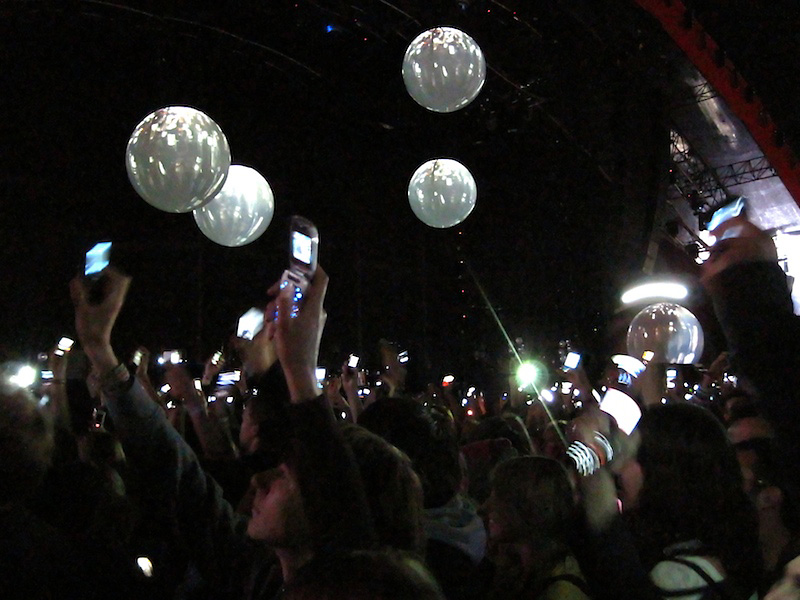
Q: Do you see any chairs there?
A: No, there are no chairs.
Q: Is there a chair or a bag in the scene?
A: No, there are no chairs or bags.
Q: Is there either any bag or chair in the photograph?
A: No, there are no chairs or bags.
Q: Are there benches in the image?
A: No, there are no benches.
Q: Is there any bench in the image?
A: No, there are no benches.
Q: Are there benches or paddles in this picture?
A: No, there are no benches or paddles.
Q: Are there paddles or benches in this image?
A: No, there are no benches or paddles.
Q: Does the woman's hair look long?
A: Yes, the hair is long.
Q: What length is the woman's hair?
A: The hair is long.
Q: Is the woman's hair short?
A: No, the hair is long.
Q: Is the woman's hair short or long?
A: The hair is long.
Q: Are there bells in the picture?
A: No, there are no bells.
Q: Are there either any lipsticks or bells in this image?
A: No, there are no bells or lipsticks.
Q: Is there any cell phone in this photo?
A: Yes, there is a cell phone.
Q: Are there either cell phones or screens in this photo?
A: Yes, there is a cell phone.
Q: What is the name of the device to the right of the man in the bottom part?
A: The device is a cell phone.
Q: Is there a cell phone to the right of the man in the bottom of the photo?
A: Yes, there is a cell phone to the right of the man.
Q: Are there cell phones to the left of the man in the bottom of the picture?
A: No, the cell phone is to the right of the man.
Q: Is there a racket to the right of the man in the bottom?
A: No, there is a cell phone to the right of the man.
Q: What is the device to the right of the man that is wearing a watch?
A: The device is a cell phone.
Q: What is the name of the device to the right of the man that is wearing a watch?
A: The device is a cell phone.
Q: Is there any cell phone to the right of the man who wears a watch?
A: Yes, there is a cell phone to the right of the man.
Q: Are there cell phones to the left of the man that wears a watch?
A: No, the cell phone is to the right of the man.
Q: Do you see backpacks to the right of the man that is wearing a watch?
A: No, there is a cell phone to the right of the man.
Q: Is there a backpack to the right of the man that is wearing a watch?
A: No, there is a cell phone to the right of the man.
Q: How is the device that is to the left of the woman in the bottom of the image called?
A: The device is a cell phone.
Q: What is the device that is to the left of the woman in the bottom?
A: The device is a cell phone.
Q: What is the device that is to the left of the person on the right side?
A: The device is a cell phone.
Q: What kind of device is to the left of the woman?
A: The device is a cell phone.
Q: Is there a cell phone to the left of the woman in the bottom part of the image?
A: Yes, there is a cell phone to the left of the woman.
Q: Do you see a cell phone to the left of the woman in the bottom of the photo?
A: Yes, there is a cell phone to the left of the woman.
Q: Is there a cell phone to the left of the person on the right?
A: Yes, there is a cell phone to the left of the woman.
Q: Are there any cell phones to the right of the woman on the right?
A: No, the cell phone is to the left of the woman.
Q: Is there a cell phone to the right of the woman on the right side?
A: No, the cell phone is to the left of the woman.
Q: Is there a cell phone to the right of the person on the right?
A: No, the cell phone is to the left of the woman.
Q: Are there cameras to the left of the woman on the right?
A: No, there is a cell phone to the left of the woman.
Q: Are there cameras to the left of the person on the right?
A: No, there is a cell phone to the left of the woman.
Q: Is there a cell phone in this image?
A: Yes, there is a cell phone.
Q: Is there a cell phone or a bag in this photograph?
A: Yes, there is a cell phone.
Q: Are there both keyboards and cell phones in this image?
A: No, there is a cell phone but no keyboards.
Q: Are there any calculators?
A: No, there are no calculators.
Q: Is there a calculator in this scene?
A: No, there are no calculators.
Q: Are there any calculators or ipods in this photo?
A: No, there are no calculators or ipods.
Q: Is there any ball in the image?
A: Yes, there is a ball.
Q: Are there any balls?
A: Yes, there is a ball.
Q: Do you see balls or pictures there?
A: Yes, there is a ball.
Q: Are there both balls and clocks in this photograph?
A: No, there is a ball but no clocks.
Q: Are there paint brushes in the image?
A: No, there are no paint brushes.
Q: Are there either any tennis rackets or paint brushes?
A: No, there are no paint brushes or tennis rackets.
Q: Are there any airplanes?
A: No, there are no airplanes.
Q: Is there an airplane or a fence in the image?
A: No, there are no airplanes or fences.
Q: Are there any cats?
A: No, there are no cats.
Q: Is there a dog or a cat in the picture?
A: No, there are no cats or dogs.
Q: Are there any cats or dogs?
A: No, there are no cats or dogs.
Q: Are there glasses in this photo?
A: No, there are no glasses.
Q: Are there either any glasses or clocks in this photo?
A: No, there are no glasses or clocks.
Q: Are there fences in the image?
A: No, there are no fences.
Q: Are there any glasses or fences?
A: No, there are no fences or glasses.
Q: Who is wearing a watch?
A: The man is wearing a watch.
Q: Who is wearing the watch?
A: The man is wearing a watch.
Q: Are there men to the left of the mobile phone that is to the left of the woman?
A: Yes, there is a man to the left of the mobile phone.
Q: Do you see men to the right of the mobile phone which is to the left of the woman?
A: No, the man is to the left of the cell phone.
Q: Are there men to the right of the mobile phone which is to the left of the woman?
A: No, the man is to the left of the cell phone.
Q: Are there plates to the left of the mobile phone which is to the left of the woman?
A: No, there is a man to the left of the cell phone.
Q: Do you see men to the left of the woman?
A: Yes, there is a man to the left of the woman.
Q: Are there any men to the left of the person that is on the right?
A: Yes, there is a man to the left of the woman.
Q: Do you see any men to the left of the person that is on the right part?
A: Yes, there is a man to the left of the woman.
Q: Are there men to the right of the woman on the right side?
A: No, the man is to the left of the woman.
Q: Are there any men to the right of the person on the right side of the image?
A: No, the man is to the left of the woman.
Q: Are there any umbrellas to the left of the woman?
A: No, there is a man to the left of the woman.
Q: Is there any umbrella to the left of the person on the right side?
A: No, there is a man to the left of the woman.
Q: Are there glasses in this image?
A: No, there are no glasses.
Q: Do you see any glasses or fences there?
A: No, there are no glasses or fences.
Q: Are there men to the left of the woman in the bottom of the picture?
A: Yes, there is a man to the left of the woman.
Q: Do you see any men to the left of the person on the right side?
A: Yes, there is a man to the left of the woman.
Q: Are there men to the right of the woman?
A: No, the man is to the left of the woman.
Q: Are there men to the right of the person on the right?
A: No, the man is to the left of the woman.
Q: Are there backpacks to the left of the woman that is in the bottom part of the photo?
A: No, there is a man to the left of the woman.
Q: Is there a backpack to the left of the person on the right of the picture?
A: No, there is a man to the left of the woman.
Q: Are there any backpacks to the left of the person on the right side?
A: No, there is a man to the left of the woman.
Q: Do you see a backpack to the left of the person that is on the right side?
A: No, there is a man to the left of the woman.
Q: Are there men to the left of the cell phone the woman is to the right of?
A: Yes, there is a man to the left of the cellphone.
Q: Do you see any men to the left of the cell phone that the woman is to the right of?
A: Yes, there is a man to the left of the cellphone.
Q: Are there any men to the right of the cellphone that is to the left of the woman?
A: No, the man is to the left of the cellphone.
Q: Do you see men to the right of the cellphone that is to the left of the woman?
A: No, the man is to the left of the cellphone.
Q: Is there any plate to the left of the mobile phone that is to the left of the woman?
A: No, there is a man to the left of the cell phone.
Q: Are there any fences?
A: No, there are no fences.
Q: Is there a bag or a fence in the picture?
A: No, there are no fences or bags.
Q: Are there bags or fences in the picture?
A: No, there are no fences or bags.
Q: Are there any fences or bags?
A: No, there are no fences or bags.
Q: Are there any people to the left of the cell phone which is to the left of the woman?
A: Yes, there is a person to the left of the cellphone.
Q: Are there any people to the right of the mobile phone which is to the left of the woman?
A: No, the person is to the left of the cellphone.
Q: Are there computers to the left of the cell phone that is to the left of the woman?
A: No, there is a person to the left of the cellphone.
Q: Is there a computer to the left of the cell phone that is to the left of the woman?
A: No, there is a person to the left of the cellphone.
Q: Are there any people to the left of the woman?
A: Yes, there is a person to the left of the woman.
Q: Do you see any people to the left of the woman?
A: Yes, there is a person to the left of the woman.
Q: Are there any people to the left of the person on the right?
A: Yes, there is a person to the left of the woman.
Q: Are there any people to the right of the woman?
A: No, the person is to the left of the woman.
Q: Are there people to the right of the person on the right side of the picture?
A: No, the person is to the left of the woman.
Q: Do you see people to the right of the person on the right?
A: No, the person is to the left of the woman.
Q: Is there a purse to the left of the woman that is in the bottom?
A: No, there is a person to the left of the woman.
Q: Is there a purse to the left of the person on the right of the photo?
A: No, there is a person to the left of the woman.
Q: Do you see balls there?
A: Yes, there is a ball.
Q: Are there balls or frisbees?
A: Yes, there is a ball.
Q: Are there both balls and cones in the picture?
A: No, there is a ball but no cones.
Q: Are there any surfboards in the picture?
A: No, there are no surfboards.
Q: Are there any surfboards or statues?
A: No, there are no surfboards or statues.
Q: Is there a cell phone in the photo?
A: Yes, there is a cell phone.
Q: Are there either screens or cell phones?
A: Yes, there is a cell phone.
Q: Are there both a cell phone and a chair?
A: No, there is a cell phone but no chairs.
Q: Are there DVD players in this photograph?
A: No, there are no DVD players.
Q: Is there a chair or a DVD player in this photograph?
A: No, there are no DVD players or chairs.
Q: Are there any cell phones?
A: Yes, there is a cell phone.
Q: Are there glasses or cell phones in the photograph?
A: Yes, there is a cell phone.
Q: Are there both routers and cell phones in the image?
A: No, there is a cell phone but no routers.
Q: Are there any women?
A: Yes, there is a woman.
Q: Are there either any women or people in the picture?
A: Yes, there is a woman.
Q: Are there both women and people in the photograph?
A: Yes, there are both a woman and a person.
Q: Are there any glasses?
A: No, there are no glasses.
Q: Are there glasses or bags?
A: No, there are no glasses or bags.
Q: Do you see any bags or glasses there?
A: No, there are no glasses or bags.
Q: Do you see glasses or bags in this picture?
A: No, there are no glasses or bags.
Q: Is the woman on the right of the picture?
A: Yes, the woman is on the right of the image.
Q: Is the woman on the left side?
A: No, the woman is on the right of the image.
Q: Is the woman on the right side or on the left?
A: The woman is on the right of the image.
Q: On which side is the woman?
A: The woman is on the right of the image.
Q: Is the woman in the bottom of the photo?
A: Yes, the woman is in the bottom of the image.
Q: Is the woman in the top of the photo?
A: No, the woman is in the bottom of the image.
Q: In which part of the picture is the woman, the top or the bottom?
A: The woman is in the bottom of the image.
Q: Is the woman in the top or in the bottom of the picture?
A: The woman is in the bottom of the image.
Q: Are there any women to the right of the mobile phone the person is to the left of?
A: Yes, there is a woman to the right of the mobile phone.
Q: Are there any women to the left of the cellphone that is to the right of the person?
A: No, the woman is to the right of the cellphone.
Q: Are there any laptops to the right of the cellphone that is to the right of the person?
A: No, there is a woman to the right of the mobile phone.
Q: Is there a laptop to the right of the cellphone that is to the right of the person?
A: No, there is a woman to the right of the mobile phone.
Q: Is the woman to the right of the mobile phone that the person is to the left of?
A: Yes, the woman is to the right of the mobile phone.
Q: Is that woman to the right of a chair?
A: No, the woman is to the right of the mobile phone.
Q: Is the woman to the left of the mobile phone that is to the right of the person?
A: No, the woman is to the right of the cellphone.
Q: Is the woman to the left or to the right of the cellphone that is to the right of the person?
A: The woman is to the right of the cellphone.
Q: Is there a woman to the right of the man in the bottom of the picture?
A: Yes, there is a woman to the right of the man.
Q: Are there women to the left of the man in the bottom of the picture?
A: No, the woman is to the right of the man.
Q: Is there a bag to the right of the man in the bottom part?
A: No, there is a woman to the right of the man.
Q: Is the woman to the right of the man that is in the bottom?
A: Yes, the woman is to the right of the man.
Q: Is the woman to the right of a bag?
A: No, the woman is to the right of the man.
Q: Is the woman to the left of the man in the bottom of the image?
A: No, the woman is to the right of the man.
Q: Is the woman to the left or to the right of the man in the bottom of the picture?
A: The woman is to the right of the man.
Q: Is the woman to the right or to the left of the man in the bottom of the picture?
A: The woman is to the right of the man.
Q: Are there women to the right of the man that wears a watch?
A: Yes, there is a woman to the right of the man.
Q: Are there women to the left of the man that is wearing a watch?
A: No, the woman is to the right of the man.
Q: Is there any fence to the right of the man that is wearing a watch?
A: No, there is a woman to the right of the man.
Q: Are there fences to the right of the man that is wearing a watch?
A: No, there is a woman to the right of the man.